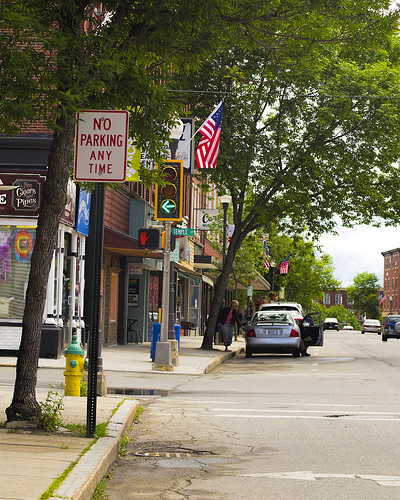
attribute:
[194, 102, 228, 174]
flag — hanging, american, red, white, blue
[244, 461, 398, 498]
arrow — white, painted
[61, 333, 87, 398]
fire hydrant — yellow, green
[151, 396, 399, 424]
crosswalk — white, stripes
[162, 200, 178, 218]
arrow — green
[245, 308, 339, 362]
car — parked, silver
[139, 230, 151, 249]
hand — red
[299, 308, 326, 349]
door — open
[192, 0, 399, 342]
tree — tall, leaning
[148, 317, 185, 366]
trash can — blue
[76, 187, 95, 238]
sign — blue